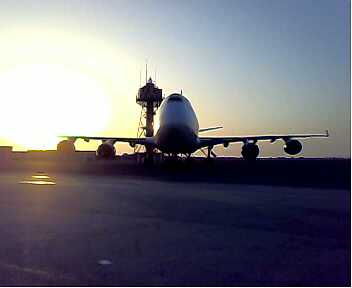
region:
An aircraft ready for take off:
[59, 90, 328, 159]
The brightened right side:
[9, 107, 81, 213]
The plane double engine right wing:
[203, 129, 334, 162]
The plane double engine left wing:
[56, 134, 156, 159]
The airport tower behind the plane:
[131, 65, 164, 161]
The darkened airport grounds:
[0, 155, 349, 286]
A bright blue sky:
[0, 0, 350, 154]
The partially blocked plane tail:
[193, 123, 225, 132]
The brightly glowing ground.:
[18, 167, 61, 188]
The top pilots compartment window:
[163, 88, 188, 104]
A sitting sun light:
[23, 63, 102, 115]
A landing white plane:
[40, 93, 324, 170]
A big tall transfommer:
[135, 64, 156, 139]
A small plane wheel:
[243, 141, 258, 159]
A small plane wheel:
[287, 141, 304, 156]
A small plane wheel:
[91, 141, 114, 156]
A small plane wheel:
[60, 141, 77, 154]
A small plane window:
[169, 92, 179, 105]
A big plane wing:
[206, 122, 331, 153]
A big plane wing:
[58, 132, 143, 154]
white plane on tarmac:
[72, 69, 288, 177]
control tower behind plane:
[123, 69, 178, 162]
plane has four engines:
[36, 119, 329, 188]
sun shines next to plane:
[34, 50, 140, 153]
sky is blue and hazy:
[218, 28, 349, 107]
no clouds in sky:
[231, 19, 350, 94]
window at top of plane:
[171, 93, 192, 112]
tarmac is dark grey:
[35, 168, 207, 271]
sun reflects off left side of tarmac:
[29, 170, 65, 208]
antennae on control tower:
[140, 59, 160, 80]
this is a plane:
[53, 91, 327, 161]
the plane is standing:
[41, 91, 340, 164]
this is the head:
[160, 112, 190, 136]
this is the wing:
[51, 121, 141, 143]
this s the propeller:
[93, 140, 119, 157]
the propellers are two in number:
[234, 137, 317, 157]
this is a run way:
[134, 181, 257, 245]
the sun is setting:
[6, 124, 47, 145]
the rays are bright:
[3, 104, 50, 134]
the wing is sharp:
[305, 127, 330, 143]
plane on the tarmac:
[179, 148, 230, 187]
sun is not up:
[7, 105, 58, 158]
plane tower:
[136, 83, 174, 126]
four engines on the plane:
[242, 150, 270, 161]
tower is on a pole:
[136, 94, 160, 136]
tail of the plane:
[175, 82, 189, 94]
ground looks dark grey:
[135, 193, 225, 232]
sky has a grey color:
[227, 24, 284, 67]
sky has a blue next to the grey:
[160, 47, 221, 65]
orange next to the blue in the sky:
[205, 105, 251, 142]